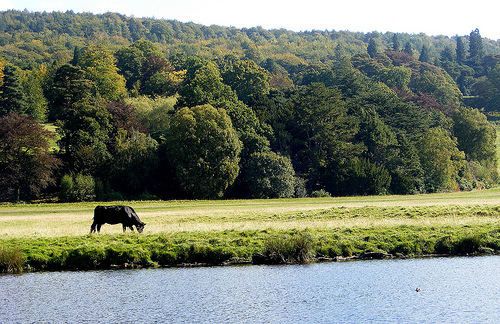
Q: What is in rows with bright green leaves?
A: Trees.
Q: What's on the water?
A: Ripples.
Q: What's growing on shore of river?
A: Grass.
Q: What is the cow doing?
A: Eating grass.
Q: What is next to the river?
A: Thick grass.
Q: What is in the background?
A: Thick forest.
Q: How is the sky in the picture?
A: Clear.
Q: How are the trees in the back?
A: Thick and dense.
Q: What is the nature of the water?
A: Calm.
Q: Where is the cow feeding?
A: Green plains.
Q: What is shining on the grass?
A: The sun.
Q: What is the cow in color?
A: Black.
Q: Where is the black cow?
A: On the grass.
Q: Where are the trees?
A: On side the road.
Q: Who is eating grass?
A: A cow.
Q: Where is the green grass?
A: On the shore.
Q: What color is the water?
A: The water is blue.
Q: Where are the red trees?
A: In the forest.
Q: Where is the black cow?
A: On the ground.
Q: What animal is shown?
A: Cow.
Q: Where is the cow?
A: Next to water.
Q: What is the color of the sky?
A: White.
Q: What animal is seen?
A: Cow.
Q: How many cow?
A: 1.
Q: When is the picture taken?
A: Daytime.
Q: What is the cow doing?
A: Eating.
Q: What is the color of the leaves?
A: Green.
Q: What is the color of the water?
A: Blue.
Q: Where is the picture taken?
A: Near a forest.